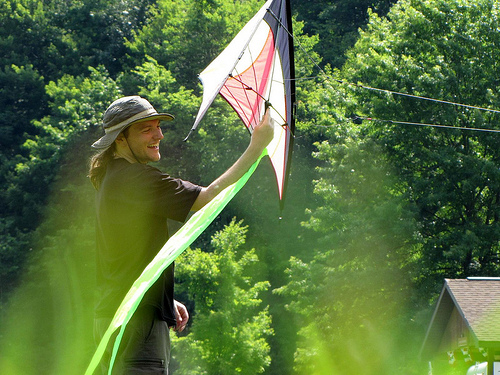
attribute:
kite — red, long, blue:
[183, 0, 296, 215]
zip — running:
[312, 75, 500, 113]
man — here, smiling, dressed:
[88, 93, 274, 375]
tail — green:
[89, 150, 268, 373]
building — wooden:
[419, 275, 500, 374]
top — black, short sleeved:
[95, 156, 201, 329]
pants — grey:
[95, 316, 175, 371]